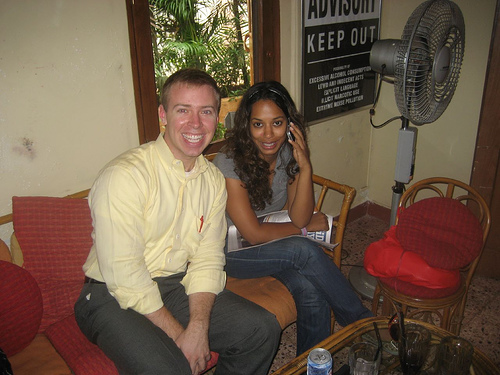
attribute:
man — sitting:
[73, 68, 282, 367]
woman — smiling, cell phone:
[217, 80, 372, 351]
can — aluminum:
[306, 345, 332, 374]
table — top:
[267, 313, 496, 374]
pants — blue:
[223, 234, 369, 356]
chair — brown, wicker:
[365, 173, 492, 341]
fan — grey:
[369, 5, 466, 237]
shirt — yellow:
[81, 135, 228, 314]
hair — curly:
[228, 80, 308, 207]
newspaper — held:
[228, 210, 337, 250]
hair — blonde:
[162, 69, 222, 114]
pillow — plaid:
[396, 198, 482, 271]